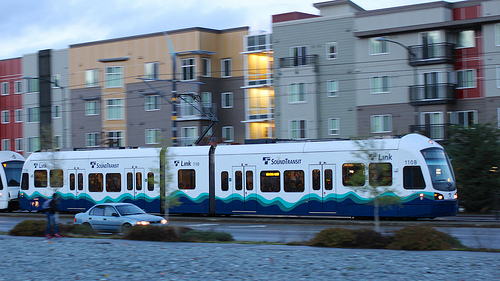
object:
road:
[0, 214, 500, 251]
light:
[264, 170, 278, 177]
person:
[42, 192, 62, 238]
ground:
[0, 208, 499, 281]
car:
[73, 203, 169, 236]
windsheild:
[420, 146, 458, 191]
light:
[489, 167, 499, 173]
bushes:
[400, 120, 499, 212]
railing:
[408, 81, 455, 101]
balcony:
[406, 82, 457, 106]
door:
[322, 164, 336, 211]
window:
[220, 92, 233, 108]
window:
[220, 58, 233, 78]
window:
[221, 125, 235, 142]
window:
[326, 81, 339, 98]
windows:
[25, 106, 40, 123]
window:
[260, 170, 281, 192]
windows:
[104, 66, 124, 88]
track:
[420, 216, 499, 222]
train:
[17, 132, 459, 221]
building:
[0, 0, 499, 160]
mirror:
[112, 212, 119, 217]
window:
[88, 173, 103, 192]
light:
[433, 192, 444, 201]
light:
[454, 193, 458, 199]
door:
[244, 165, 257, 210]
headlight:
[141, 220, 150, 225]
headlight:
[161, 219, 168, 224]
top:
[28, 132, 444, 159]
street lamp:
[373, 36, 416, 57]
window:
[369, 113, 392, 133]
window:
[289, 120, 308, 139]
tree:
[334, 122, 402, 251]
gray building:
[273, 0, 500, 140]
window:
[286, 81, 307, 105]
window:
[460, 30, 475, 50]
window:
[325, 42, 339, 61]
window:
[327, 118, 340, 135]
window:
[368, 35, 391, 56]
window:
[369, 75, 392, 94]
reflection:
[30, 201, 39, 207]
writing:
[262, 157, 302, 166]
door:
[310, 164, 323, 212]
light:
[136, 221, 141, 225]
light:
[250, 55, 268, 60]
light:
[251, 88, 272, 95]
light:
[250, 122, 269, 127]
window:
[144, 94, 160, 112]